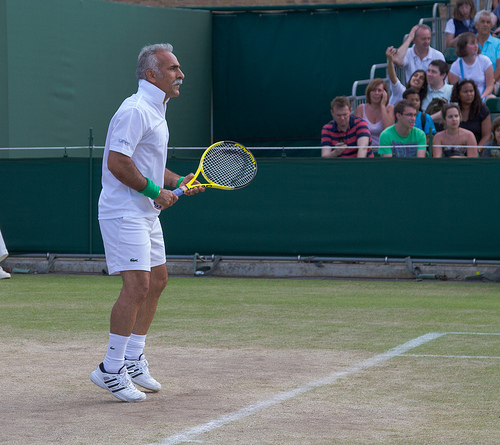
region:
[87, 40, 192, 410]
An older man with grey hair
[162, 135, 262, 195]
A black and yellow tennis racket with a blue handle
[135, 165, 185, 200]
Green arm bands.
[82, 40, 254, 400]
A man holding a tennis racket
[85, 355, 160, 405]
White and black tennis shoes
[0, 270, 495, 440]
A tennis court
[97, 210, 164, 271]
White sport shorts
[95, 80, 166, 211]
A white short sleeved shirt with a collar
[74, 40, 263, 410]
A tennis player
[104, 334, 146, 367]
Long white socks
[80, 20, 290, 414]
man is holdign a racket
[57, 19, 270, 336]
man is holdign a racket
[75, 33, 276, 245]
man is holdign a racket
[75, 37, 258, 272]
man is holdign a racket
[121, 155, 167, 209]
the wrist band is green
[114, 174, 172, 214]
the wrist band is green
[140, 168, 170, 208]
the wrist band is green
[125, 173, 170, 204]
the wrist band is green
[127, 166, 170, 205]
the wrist band is green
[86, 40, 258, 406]
a man playing tennis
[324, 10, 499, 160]
a crowd of spectators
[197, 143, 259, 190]
a yellow tennis racket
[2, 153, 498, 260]
a green fence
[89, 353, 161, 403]
white athletic shoes with black stripes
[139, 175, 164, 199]
a green arm sweat band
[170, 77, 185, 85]
a thick gray mustache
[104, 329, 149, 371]
white sport socks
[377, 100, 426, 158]
the man is wearing a green t-shirt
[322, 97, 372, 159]
The man is weaaring a black and red striped shirt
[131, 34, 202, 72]
Man has short hair.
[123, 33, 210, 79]
Man has gray hair.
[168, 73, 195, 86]
Man has gray mustache.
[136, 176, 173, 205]
Green band around man's wrist.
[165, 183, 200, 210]
Blue grip on tennis racket.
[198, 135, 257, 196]
Tennis racket is yellow and black.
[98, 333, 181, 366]
Man wearing white socks.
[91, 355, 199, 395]
Man wearing white tennis shoes.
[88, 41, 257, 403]
a tennis playing standing on his toes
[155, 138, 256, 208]
a yellow and gray tennis racket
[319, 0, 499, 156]
people watching a tennis match in the bleachers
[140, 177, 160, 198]
man wearing a green wristband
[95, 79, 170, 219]
man wearing a white polo shirt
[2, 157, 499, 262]
green tarp on a fence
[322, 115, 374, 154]
man wearing a red and blue stripe shirt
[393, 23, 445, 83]
a man touching his head with his hand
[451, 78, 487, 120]
woman with long brown hair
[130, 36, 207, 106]
the head of a man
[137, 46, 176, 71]
the hair of a man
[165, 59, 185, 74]
the eyes of a man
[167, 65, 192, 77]
the nose of a man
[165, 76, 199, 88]
the mustache of a man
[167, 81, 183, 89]
the mouth of a man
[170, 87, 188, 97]
the chin of a man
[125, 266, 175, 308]
the knees of a man